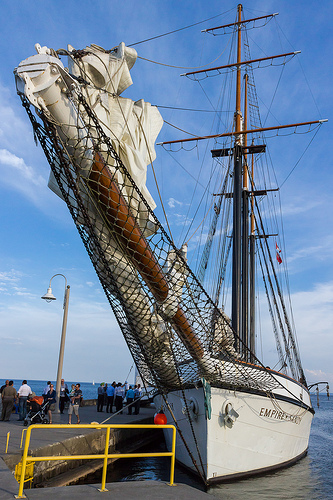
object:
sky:
[0, 0, 333, 407]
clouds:
[0, 81, 332, 397]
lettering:
[258, 407, 303, 425]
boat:
[13, 1, 328, 494]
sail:
[154, 2, 327, 385]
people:
[0, 379, 17, 424]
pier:
[0, 396, 214, 499]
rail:
[16, 420, 179, 499]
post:
[52, 283, 71, 417]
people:
[42, 380, 57, 426]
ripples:
[79, 409, 333, 499]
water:
[74, 391, 332, 499]